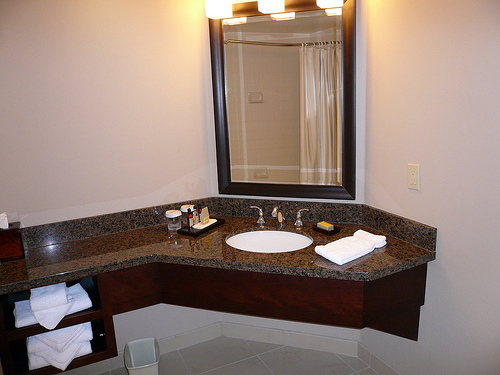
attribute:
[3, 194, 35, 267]
tissues — box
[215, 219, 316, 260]
bowl — white, sink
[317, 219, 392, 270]
towel — white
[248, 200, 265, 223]
knob — silver, hot, water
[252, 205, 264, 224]
faucet fixture — silver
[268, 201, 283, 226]
faucet fixture — silver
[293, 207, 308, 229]
faucet fixture — silver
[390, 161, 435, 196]
outlet — electrical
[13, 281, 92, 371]
towels — folded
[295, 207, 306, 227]
knob — silver, cold, water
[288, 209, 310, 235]
handle — silver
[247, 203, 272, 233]
handle — silver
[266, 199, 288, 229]
water faucet — silver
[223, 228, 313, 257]
sink — white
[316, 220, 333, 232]
soap — bar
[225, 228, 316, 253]
sink — bathroom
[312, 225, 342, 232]
dish — small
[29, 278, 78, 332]
towels — folded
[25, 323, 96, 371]
towels — folded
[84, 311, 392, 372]
baseboard — white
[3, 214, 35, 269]
box — tissues